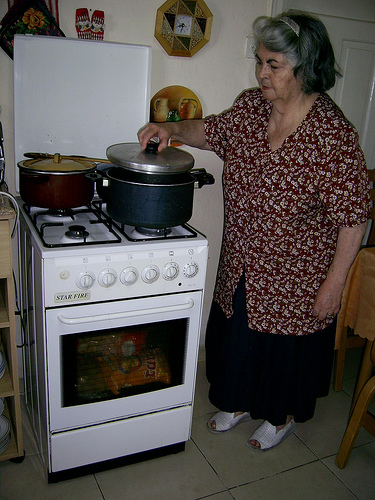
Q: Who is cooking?
A: Woman.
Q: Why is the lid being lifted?
A: To check the food.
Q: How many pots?
A: Two.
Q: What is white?
A: Stove.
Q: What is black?
A: Skirt.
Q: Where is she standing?
A: Kitchen.